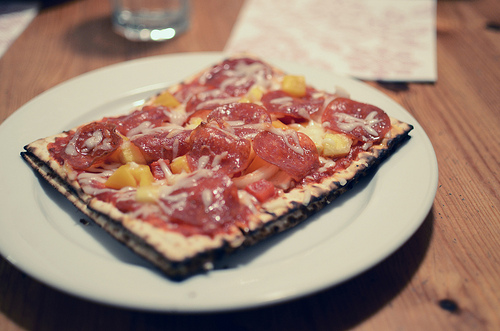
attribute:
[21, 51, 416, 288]
slice pizza — small, square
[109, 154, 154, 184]
topping — yellow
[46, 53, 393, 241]
toppings — yellow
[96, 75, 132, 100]
plate — circular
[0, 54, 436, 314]
plate — white, with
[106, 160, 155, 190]
cheese — yellow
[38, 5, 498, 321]
table — brown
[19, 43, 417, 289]
flatbread — burnt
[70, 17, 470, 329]
plate — round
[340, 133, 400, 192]
bread — burnt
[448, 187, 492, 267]
table — wood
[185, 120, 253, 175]
topping — red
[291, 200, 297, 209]
black — color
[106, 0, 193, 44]
glass — drinking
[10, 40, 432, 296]
plate — white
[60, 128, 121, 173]
pepperoni — small